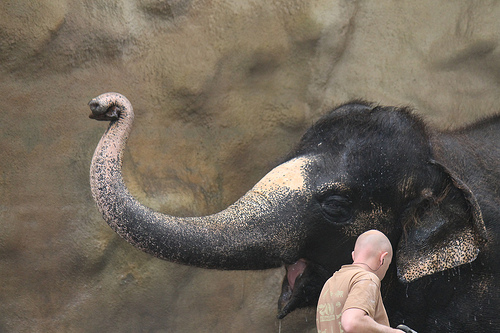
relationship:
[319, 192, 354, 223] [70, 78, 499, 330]
eye of elephant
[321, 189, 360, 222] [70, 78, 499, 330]
eye on elephant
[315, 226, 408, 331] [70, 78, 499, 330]
handler near elephant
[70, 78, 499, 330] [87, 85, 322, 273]
elephant holding up trunk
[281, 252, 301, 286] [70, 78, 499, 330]
tongue on elephant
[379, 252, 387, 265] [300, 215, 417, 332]
ear of person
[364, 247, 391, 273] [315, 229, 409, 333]
ear of handler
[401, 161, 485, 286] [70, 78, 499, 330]
ear of elephant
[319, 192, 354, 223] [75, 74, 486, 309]
eye of elephant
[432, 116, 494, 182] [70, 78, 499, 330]
back of elephant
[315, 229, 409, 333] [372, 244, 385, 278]
handler wearing headphones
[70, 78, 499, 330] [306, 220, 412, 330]
elephant near handler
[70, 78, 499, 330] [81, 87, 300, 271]
elephant raising trunk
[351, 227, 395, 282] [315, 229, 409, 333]
shaved head on handler